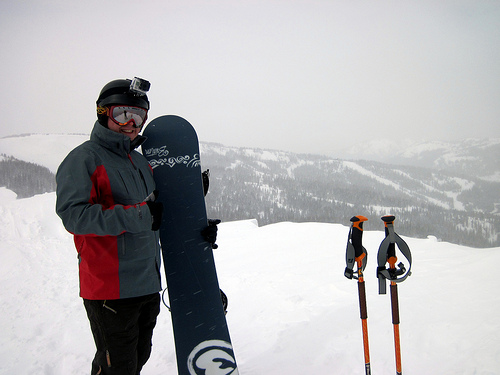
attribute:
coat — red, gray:
[47, 120, 167, 297]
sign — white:
[149, 145, 209, 172]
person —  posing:
[47, 61, 173, 372]